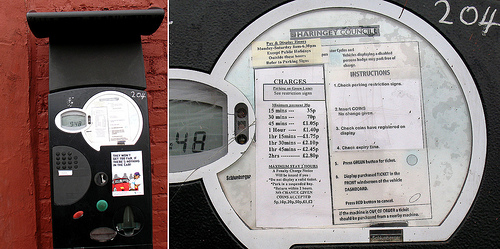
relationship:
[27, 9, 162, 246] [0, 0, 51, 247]
machine against wall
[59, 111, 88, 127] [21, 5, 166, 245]
timer on meter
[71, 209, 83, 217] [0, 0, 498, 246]
button on meter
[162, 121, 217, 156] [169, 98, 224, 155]
digital numbers on screen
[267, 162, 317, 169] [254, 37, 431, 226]
writing on paper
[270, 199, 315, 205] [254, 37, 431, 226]
writing on paper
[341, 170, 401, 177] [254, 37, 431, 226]
writing on paper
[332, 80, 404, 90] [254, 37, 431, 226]
writing on paper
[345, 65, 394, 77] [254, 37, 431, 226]
writing on paper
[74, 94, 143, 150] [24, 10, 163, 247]
sticker on parking meter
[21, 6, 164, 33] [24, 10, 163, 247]
top on parking meter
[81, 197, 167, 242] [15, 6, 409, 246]
slots in meter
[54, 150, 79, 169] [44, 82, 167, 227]
buttons mounted on meter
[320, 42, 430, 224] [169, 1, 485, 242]
instructions printed on parking meter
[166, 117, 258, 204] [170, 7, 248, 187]
crack appearing on meter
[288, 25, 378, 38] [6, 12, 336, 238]
name printed on meter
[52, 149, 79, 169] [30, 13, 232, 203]
control panel mounted on device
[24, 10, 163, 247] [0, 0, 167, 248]
parking meter standing near wall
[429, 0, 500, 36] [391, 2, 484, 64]
handwritten numbers written in corner